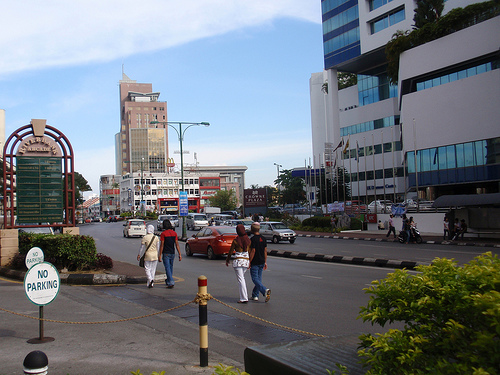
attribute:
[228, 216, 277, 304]
people — walking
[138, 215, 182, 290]
people — walking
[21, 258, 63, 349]
sign — round, no parking sign, small, white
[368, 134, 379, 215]
flag pole — flag pole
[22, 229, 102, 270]
bush — green, brown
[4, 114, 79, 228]
sign — large, stone, showing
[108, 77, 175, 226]
building — brown, large, wide, tall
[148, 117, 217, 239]
street lights — two sided, large, street lights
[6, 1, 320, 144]
sky — blue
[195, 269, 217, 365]
pole — chain pole, orange, metal, red, black, yellow, striped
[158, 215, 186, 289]
person — walking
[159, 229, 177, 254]
jacket — blue, red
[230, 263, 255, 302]
pants — white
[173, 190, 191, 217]
street sign — white, blue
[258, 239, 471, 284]
divider — black, white, gray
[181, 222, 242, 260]
car — luxury, red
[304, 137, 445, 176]
flags — various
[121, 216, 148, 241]
vehicle — white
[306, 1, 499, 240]
building — white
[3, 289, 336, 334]
ropes — closing off